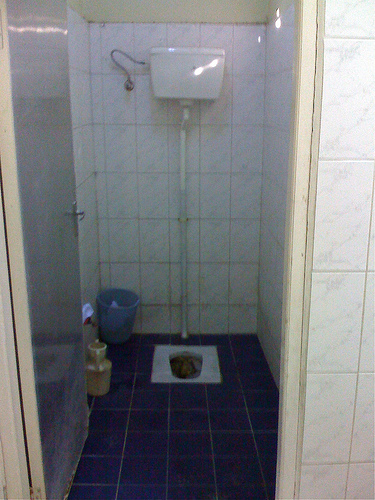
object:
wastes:
[170, 352, 197, 377]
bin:
[94, 285, 142, 349]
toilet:
[149, 340, 222, 383]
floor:
[67, 332, 280, 498]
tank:
[148, 43, 225, 103]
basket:
[95, 286, 140, 346]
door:
[1, 0, 90, 499]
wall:
[87, 21, 260, 333]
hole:
[169, 350, 203, 379]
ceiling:
[69, 1, 274, 24]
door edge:
[1, 96, 34, 500]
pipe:
[178, 103, 189, 341]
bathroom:
[0, 1, 294, 500]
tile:
[214, 456, 263, 486]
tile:
[228, 332, 260, 348]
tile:
[135, 344, 152, 375]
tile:
[126, 408, 171, 433]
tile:
[74, 454, 124, 488]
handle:
[76, 209, 85, 222]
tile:
[101, 123, 136, 176]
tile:
[233, 25, 265, 78]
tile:
[100, 76, 136, 123]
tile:
[231, 75, 268, 127]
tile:
[134, 123, 170, 176]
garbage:
[109, 297, 120, 309]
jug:
[85, 339, 113, 396]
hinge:
[28, 488, 37, 500]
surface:
[34, 76, 53, 159]